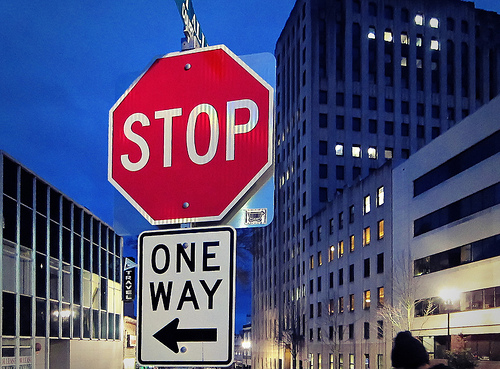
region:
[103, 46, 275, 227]
a red STOP traffic sign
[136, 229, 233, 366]
a ONE WAY traffic sign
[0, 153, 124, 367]
a building in distance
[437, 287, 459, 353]
an overhead street light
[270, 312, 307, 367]
a bare leafed tree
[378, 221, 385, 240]
glass window on building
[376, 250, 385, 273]
glass window on building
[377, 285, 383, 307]
glass window on building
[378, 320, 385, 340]
glass window on building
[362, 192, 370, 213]
glass window on building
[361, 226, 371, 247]
glass window on building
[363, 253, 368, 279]
glass window on building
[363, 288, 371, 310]
glass window on building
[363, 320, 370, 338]
glass window on building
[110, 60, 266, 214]
a red STOP sign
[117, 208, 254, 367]
a one way sign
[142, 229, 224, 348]
a one way sign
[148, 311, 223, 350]
the arrow is black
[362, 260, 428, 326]
the tree is bare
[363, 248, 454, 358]
the tree is bare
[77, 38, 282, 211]
red and white sign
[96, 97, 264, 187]
white letters on sign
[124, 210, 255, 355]
black and white sign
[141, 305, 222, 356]
black arrow on sign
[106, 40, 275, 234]
STOP sign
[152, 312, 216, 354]
Arrow pointing left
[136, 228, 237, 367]
One Way sign under the STOP sign